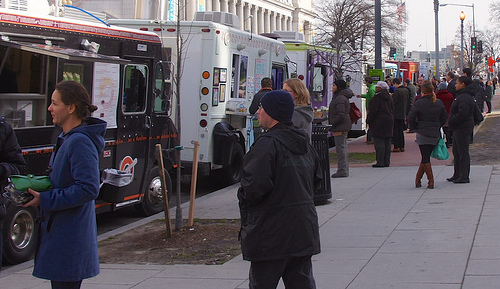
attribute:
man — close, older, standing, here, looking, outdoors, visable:
[241, 93, 328, 289]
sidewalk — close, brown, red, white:
[358, 188, 491, 285]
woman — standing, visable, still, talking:
[31, 87, 115, 283]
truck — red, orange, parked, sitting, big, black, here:
[88, 29, 191, 217]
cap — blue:
[258, 89, 296, 123]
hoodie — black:
[265, 123, 311, 158]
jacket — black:
[236, 120, 319, 261]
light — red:
[202, 87, 210, 95]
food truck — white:
[107, 18, 297, 183]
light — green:
[392, 52, 399, 60]